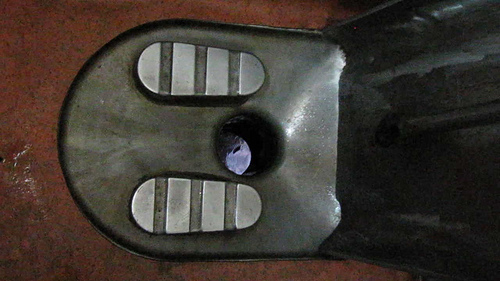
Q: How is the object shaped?
A: Oblong.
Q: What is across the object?
A: Ridges.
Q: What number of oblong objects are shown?
A: Two.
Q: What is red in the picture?
A: The background.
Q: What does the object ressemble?
A: A shoe.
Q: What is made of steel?
A: The footrest.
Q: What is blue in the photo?
A: The center item.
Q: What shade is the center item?
A: Blue.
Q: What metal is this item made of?
A: Steel.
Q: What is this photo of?
A: A steel pad.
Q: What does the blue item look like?
A: The moon.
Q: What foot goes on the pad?
A: Both feet.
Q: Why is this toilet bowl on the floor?
A: It's metal.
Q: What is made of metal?
A: The toilet bowl.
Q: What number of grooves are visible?
A: Three.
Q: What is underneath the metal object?
A: A brown floor.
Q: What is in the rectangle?
A: Dark gray portion of metal object.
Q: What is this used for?
A: A place to put foot.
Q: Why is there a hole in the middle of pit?
A: To dispose waste products.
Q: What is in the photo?
A: A toilet pit.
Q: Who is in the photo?
A: No one.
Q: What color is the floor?
A: Brown.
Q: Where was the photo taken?
A: In a public bathroom.